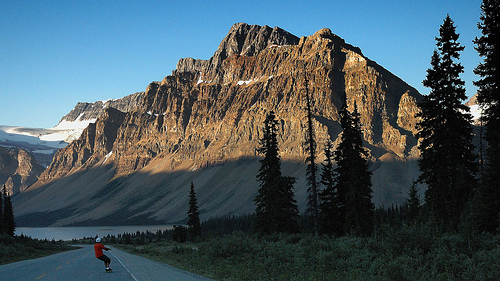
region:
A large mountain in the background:
[46, 15, 437, 202]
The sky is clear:
[0, 0, 493, 120]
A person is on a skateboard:
[87, 231, 117, 276]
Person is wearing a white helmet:
[86, 226, 106, 241]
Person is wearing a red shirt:
[81, 240, 107, 260]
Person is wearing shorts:
[85, 250, 115, 265]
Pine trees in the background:
[170, 5, 495, 240]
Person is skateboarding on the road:
[2, 225, 204, 279]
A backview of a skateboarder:
[75, 230, 130, 275]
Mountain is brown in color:
[28, 17, 432, 209]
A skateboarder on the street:
[89, 235, 119, 274]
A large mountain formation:
[71, 17, 441, 169]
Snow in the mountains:
[6, 103, 118, 166]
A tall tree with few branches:
[298, 78, 328, 234]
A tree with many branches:
[423, 16, 480, 228]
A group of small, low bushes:
[212, 237, 399, 280]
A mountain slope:
[36, 167, 208, 229]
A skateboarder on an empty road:
[56, 237, 129, 277]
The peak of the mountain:
[227, 21, 276, 49]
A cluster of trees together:
[255, 78, 380, 238]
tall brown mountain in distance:
[57, 25, 369, 180]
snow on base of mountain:
[44, 89, 111, 140]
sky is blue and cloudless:
[0, 1, 91, 143]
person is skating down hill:
[87, 230, 119, 273]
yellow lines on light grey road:
[35, 224, 110, 272]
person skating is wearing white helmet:
[89, 233, 113, 248]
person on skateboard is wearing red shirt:
[89, 243, 108, 255]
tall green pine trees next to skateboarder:
[157, 18, 494, 235]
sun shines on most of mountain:
[147, 55, 362, 160]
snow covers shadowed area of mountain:
[66, 160, 280, 221]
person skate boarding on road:
[83, 236, 127, 271]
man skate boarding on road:
[86, 236, 116, 273]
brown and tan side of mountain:
[35, 165, 105, 199]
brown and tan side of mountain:
[112, 162, 182, 193]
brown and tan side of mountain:
[206, 165, 260, 213]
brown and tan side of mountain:
[372, 102, 410, 182]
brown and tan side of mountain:
[119, 113, 194, 143]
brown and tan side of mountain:
[207, 86, 269, 144]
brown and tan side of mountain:
[257, 46, 318, 90]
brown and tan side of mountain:
[207, 56, 251, 100]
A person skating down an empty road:
[70, 230, 125, 275]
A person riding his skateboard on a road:
[75, 230, 120, 275]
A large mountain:
[10, 0, 430, 220]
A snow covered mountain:
[25, 95, 115, 160]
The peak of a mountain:
[215, 0, 325, 100]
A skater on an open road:
[60, 220, 115, 275]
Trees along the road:
[240, 60, 390, 225]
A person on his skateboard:
[82, 230, 112, 275]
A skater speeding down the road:
[78, 228, 138, 279]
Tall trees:
[422, 8, 498, 256]